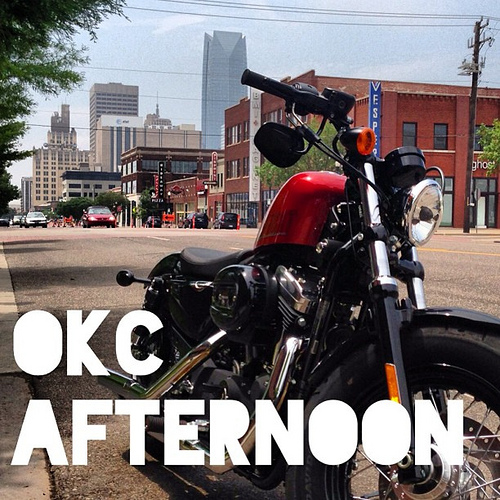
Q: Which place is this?
A: It is a road.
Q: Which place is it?
A: It is a road.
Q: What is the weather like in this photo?
A: It is overcast.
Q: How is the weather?
A: It is overcast.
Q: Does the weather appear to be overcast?
A: Yes, it is overcast.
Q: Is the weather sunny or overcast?
A: It is overcast.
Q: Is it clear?
A: No, it is overcast.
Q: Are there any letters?
A: Yes, there are letters.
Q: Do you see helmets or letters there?
A: Yes, there are letters.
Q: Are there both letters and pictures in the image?
A: No, there are letters but no pictures.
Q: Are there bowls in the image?
A: No, there are no bowls.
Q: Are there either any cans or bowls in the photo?
A: No, there are no bowls or cans.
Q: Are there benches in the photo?
A: No, there are no benches.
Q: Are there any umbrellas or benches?
A: No, there are no benches or umbrellas.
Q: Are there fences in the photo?
A: No, there are no fences.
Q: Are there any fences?
A: No, there are no fences.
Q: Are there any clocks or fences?
A: No, there are no fences or clocks.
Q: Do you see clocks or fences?
A: No, there are no fences or clocks.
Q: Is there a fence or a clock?
A: No, there are no fences or clocks.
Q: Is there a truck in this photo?
A: No, there are no trucks.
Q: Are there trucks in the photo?
A: No, there are no trucks.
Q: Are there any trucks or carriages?
A: No, there are no trucks or carriages.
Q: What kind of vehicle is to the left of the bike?
A: The vehicle is a car.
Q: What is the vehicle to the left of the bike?
A: The vehicle is a car.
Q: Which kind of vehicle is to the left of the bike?
A: The vehicle is a car.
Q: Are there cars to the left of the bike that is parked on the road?
A: Yes, there is a car to the left of the bike.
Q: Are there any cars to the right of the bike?
A: No, the car is to the left of the bike.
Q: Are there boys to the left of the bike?
A: No, there is a car to the left of the bike.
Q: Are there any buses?
A: No, there are no buses.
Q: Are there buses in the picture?
A: No, there are no buses.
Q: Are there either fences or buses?
A: No, there are no buses or fences.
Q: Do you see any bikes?
A: Yes, there is a bike.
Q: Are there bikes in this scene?
A: Yes, there is a bike.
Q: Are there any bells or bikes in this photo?
A: Yes, there is a bike.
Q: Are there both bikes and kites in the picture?
A: No, there is a bike but no kites.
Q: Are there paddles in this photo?
A: No, there are no paddles.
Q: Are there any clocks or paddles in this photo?
A: No, there are no paddles or clocks.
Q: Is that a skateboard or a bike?
A: That is a bike.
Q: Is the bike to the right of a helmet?
A: No, the bike is to the right of a car.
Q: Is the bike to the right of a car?
A: Yes, the bike is to the right of a car.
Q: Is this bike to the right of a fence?
A: No, the bike is to the right of a car.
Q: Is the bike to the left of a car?
A: No, the bike is to the right of a car.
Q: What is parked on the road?
A: The bike is parked on the road.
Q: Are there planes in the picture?
A: No, there are no planes.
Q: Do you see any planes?
A: No, there are no planes.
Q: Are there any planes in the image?
A: No, there are no planes.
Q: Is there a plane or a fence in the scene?
A: No, there are no airplanes or fences.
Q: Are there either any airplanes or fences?
A: No, there are no airplanes or fences.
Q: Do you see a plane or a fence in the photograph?
A: No, there are no airplanes or fences.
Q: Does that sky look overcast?
A: Yes, the sky is overcast.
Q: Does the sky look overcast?
A: Yes, the sky is overcast.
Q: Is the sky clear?
A: No, the sky is overcast.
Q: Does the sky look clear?
A: No, the sky is overcast.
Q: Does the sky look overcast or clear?
A: The sky is overcast.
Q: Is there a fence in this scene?
A: No, there are no fences.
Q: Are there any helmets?
A: No, there are no helmets.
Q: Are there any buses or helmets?
A: No, there are no helmets or buses.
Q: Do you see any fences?
A: No, there are no fences.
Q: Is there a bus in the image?
A: No, there are no buses.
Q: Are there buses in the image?
A: No, there are no buses.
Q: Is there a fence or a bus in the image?
A: No, there are no buses or fences.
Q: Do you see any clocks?
A: No, there are no clocks.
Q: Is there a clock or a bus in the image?
A: No, there are no clocks or buses.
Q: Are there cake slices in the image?
A: No, there are no cake slices.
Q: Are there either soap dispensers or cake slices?
A: No, there are no cake slices or soap dispensers.